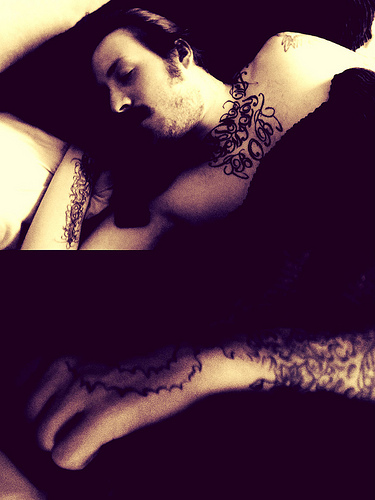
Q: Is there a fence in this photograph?
A: No, there are no fences.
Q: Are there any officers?
A: No, there are no officers.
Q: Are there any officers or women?
A: No, there are no officers or women.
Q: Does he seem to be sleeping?
A: Yes, the man is sleeping.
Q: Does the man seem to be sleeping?
A: Yes, the man is sleeping.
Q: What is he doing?
A: The man is sleeping.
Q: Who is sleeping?
A: The man is sleeping.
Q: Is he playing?
A: No, the man is sleeping.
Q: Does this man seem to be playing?
A: No, the man is sleeping.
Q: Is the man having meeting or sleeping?
A: The man is sleeping.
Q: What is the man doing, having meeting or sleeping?
A: The man is sleeping.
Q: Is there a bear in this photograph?
A: No, there are no bears.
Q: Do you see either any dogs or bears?
A: No, there are no bears or dogs.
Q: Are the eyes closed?
A: Yes, the eyes are closed.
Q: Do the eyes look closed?
A: Yes, the eyes are closed.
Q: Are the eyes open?
A: No, the eyes are closed.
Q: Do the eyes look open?
A: No, the eyes are closed.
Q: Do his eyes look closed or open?
A: The eyes are closed.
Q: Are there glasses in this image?
A: No, there are no glasses.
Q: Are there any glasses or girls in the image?
A: No, there are no glasses or girls.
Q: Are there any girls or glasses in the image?
A: No, there are no glasses or girls.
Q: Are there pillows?
A: Yes, there is a pillow.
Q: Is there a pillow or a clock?
A: Yes, there is a pillow.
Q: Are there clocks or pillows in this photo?
A: Yes, there is a pillow.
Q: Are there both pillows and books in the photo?
A: No, there is a pillow but no books.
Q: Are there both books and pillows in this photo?
A: No, there is a pillow but no books.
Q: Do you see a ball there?
A: No, there are no balls.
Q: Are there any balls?
A: No, there are no balls.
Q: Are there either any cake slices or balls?
A: No, there are no balls or cake slices.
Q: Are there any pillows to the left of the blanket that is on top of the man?
A: Yes, there is a pillow to the left of the blanket.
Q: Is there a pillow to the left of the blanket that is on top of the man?
A: Yes, there is a pillow to the left of the blanket.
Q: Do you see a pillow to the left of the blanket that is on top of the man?
A: Yes, there is a pillow to the left of the blanket.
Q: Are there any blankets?
A: Yes, there is a blanket.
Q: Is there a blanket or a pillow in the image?
A: Yes, there is a blanket.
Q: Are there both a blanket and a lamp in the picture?
A: No, there is a blanket but no lamps.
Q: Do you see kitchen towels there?
A: No, there are no kitchen towels.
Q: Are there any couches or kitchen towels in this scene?
A: No, there are no kitchen towels or couches.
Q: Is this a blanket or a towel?
A: This is a blanket.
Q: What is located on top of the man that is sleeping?
A: The blanket is on top of the man.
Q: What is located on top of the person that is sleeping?
A: The blanket is on top of the man.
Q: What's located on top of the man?
A: The blanket is on top of the man.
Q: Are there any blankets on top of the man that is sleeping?
A: Yes, there is a blanket on top of the man.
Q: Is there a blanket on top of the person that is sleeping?
A: Yes, there is a blanket on top of the man.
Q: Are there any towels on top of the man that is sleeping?
A: No, there is a blanket on top of the man.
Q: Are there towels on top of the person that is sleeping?
A: No, there is a blanket on top of the man.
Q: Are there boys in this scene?
A: No, there are no boys.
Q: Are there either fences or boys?
A: No, there are no boys or fences.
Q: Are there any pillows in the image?
A: Yes, there is a pillow.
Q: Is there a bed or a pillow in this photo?
A: Yes, there is a pillow.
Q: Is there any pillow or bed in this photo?
A: Yes, there is a pillow.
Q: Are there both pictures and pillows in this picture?
A: Yes, there are both a pillow and a picture.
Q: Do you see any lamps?
A: No, there are no lamps.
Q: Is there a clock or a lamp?
A: No, there are no lamps or clocks.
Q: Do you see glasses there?
A: No, there are no glasses.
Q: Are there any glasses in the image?
A: No, there are no glasses.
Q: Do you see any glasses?
A: No, there are no glasses.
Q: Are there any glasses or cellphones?
A: No, there are no glasses or cellphones.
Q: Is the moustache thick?
A: Yes, the moustache is thick.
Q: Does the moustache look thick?
A: Yes, the moustache is thick.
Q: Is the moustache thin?
A: No, the moustache is thick.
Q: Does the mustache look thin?
A: No, the mustache is thick.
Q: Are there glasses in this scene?
A: No, there are no glasses.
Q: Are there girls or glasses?
A: No, there are no glasses or girls.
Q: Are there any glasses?
A: No, there are no glasses.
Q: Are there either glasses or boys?
A: No, there are no glasses or boys.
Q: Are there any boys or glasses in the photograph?
A: No, there are no glasses or boys.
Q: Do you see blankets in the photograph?
A: Yes, there is a blanket.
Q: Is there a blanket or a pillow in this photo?
A: Yes, there is a blanket.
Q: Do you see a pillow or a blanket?
A: Yes, there is a blanket.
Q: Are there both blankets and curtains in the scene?
A: No, there is a blanket but no curtains.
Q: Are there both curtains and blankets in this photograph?
A: No, there is a blanket but no curtains.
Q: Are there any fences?
A: No, there are no fences.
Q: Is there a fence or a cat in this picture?
A: No, there are no fences or cats.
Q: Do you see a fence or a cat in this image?
A: No, there are no fences or cats.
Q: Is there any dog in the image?
A: No, there are no dogs.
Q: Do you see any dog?
A: No, there are no dogs.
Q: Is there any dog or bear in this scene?
A: No, there are no dogs or bears.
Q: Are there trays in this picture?
A: No, there are no trays.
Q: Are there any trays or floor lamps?
A: No, there are no trays or floor lamps.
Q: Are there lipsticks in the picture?
A: No, there are no lipsticks.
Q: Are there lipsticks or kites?
A: No, there are no lipsticks or kites.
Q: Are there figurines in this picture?
A: No, there are no figurines.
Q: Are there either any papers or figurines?
A: No, there are no figurines or papers.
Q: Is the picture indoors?
A: Yes, the picture is indoors.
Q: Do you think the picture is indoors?
A: Yes, the picture is indoors.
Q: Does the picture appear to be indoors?
A: Yes, the picture is indoors.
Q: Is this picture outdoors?
A: No, the picture is indoors.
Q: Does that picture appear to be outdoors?
A: No, the picture is indoors.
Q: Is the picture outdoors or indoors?
A: The picture is indoors.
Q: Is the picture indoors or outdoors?
A: The picture is indoors.